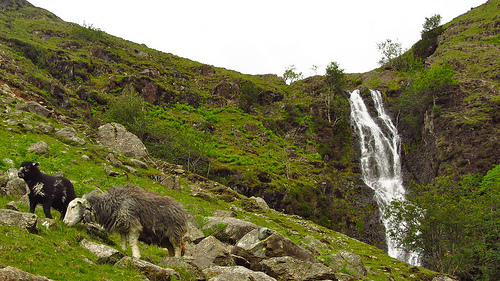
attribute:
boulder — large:
[86, 112, 156, 172]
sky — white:
[93, 5, 414, 45]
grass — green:
[67, 146, 105, 185]